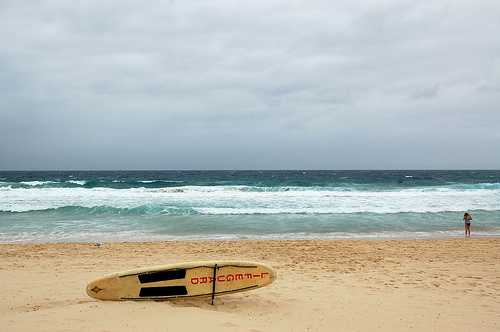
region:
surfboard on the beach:
[53, 180, 312, 330]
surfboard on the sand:
[54, 210, 303, 331]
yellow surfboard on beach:
[62, 212, 275, 329]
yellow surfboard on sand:
[71, 215, 335, 323]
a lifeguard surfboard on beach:
[62, 223, 302, 327]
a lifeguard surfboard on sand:
[57, 217, 297, 330]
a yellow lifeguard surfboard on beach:
[68, 224, 275, 330]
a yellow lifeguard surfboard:
[64, 207, 282, 329]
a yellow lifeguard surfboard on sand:
[74, 235, 297, 299]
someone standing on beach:
[400, 182, 496, 245]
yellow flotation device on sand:
[65, 233, 327, 305]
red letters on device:
[187, 261, 277, 285]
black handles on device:
[122, 258, 197, 303]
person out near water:
[452, 207, 495, 254]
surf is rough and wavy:
[58, 181, 418, 233]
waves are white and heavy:
[196, 186, 391, 232]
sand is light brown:
[45, 263, 75, 329]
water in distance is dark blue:
[224, 156, 315, 181]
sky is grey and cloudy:
[125, 13, 256, 114]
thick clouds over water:
[65, 17, 217, 138]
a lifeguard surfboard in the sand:
[80, 243, 295, 326]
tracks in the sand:
[300, 232, 406, 287]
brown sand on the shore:
[310, 251, 430, 329]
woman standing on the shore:
[435, 205, 481, 252]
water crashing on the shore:
[233, 212, 354, 242]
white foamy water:
[47, 177, 189, 212]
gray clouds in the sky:
[155, 67, 327, 125]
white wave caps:
[34, 173, 110, 185]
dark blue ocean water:
[185, 161, 337, 187]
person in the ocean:
[250, 179, 303, 214]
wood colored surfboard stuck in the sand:
[67, 241, 291, 309]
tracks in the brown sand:
[316, 235, 388, 274]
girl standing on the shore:
[450, 206, 476, 251]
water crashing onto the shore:
[292, 215, 368, 256]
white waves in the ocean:
[37, 180, 206, 221]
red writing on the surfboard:
[180, 265, 272, 292]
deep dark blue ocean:
[252, 157, 356, 186]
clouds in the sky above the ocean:
[151, 32, 363, 109]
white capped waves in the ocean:
[90, 166, 181, 186]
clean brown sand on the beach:
[316, 286, 405, 323]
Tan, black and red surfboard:
[67, 260, 311, 311]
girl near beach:
[423, 174, 498, 242]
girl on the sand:
[434, 198, 496, 257]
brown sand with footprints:
[294, 239, 496, 325]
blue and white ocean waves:
[6, 149, 444, 248]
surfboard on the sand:
[84, 250, 313, 319]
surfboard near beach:
[70, 197, 306, 305]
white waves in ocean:
[2, 182, 140, 211]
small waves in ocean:
[8, 176, 238, 237]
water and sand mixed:
[266, 220, 402, 250]